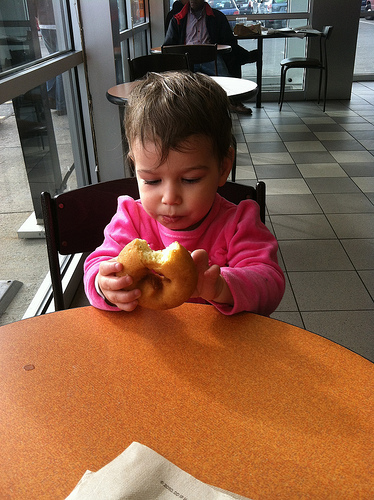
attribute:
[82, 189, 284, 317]
sweater — pink, long sleeve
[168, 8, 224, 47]
shirt — white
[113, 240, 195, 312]
donut — bite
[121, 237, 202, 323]
donut — plain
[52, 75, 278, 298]
girl — little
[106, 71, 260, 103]
empty table — orange, black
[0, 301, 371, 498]
table — orange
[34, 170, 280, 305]
chair — black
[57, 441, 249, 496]
napkin — white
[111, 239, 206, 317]
donut — brown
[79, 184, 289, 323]
shirt — pink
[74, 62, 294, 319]
girl — little, brown haired, young, sitting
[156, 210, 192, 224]
mouth — red